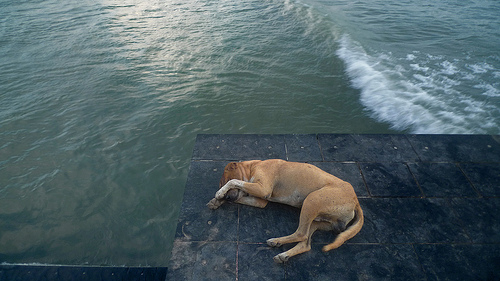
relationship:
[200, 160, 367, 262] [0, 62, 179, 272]
dog near water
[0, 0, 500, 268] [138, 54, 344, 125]
ocean waves in water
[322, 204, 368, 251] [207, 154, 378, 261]
tail of dog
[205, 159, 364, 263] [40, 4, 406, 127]
dog lying down near water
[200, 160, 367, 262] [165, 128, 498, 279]
dog lying on platform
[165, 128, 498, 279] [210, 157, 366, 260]
platform under dog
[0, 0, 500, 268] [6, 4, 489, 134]
ocean waves in water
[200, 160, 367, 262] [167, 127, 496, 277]
dog on ground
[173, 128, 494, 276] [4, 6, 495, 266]
stone in water